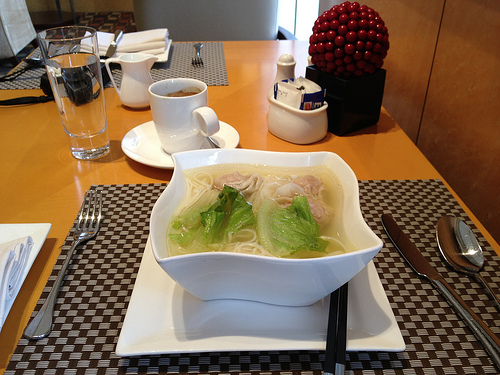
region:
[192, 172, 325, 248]
soup including noodles, meat, and a leafy green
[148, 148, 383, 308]
bowl has an unusual, flowing design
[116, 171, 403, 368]
bowl sitting in square plate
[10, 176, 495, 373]
black and grey checked place mat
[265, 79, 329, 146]
packets of sweetener in a rounded container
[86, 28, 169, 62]
knife resting on a napkin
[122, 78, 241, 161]
a cup in a saucer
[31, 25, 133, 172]
a glass with clear liquid on the table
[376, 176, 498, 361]
knife and spoon on place mat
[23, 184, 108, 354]
fork near edge of place mat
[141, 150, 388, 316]
a white bowl filled with soup.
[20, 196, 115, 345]
a metal fork on a placemat.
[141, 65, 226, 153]
a cup on a white plate.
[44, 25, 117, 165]
a glass filled with water.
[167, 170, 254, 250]
a green veggie in a soup.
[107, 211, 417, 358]
a white plate on a table.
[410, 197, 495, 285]
a silver spoon on a table.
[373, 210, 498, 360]
a knife sitting near a spoon.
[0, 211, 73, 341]
a white plate on a table.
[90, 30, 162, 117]
a pitcher on a stable.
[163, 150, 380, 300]
soup in square bowl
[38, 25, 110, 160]
glass of water on table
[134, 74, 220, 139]
cup of coffee on table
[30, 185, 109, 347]
silver fork on table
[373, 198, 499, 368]
silver utensils on table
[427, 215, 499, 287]
silver spoon on placemat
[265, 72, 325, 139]
sugar in compote on table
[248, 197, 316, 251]
cabbage in soup bowl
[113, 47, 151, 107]
white creamer on table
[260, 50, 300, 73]
salt shaker on table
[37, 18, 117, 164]
a glass of water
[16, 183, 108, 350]
a sliver fork on a woven placemat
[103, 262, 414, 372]
black chopsticks on a white plate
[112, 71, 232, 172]
a white mug on a white plate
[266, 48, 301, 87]
a white salt shaker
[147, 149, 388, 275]
soup in a white dish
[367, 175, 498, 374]
knife and spoon on a woven place mat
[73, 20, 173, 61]
knife on a stack of napkins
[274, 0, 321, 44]
a window in the background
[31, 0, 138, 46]
a table stand on a rug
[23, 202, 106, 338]
A gray fork on the table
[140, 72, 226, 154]
A cup of coffee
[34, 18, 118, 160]
A glass of water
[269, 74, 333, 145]
A cannister of sugar packets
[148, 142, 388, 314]
A bowl of soup with lettuce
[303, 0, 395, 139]
A red ball for decoration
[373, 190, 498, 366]
A knife and spoon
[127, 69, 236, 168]
A white cup on a white plate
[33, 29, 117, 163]
A white glass of water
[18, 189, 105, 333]
A silver fork on a table